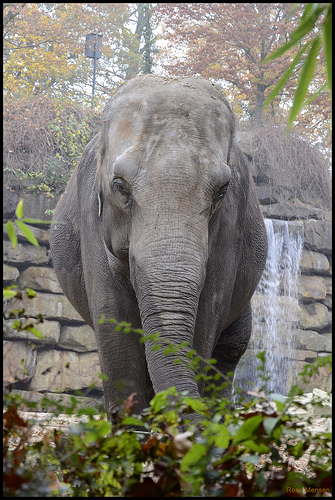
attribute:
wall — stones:
[2, 174, 334, 418]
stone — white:
[4, 240, 49, 267]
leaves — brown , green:
[89, 398, 226, 461]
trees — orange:
[172, 23, 281, 89]